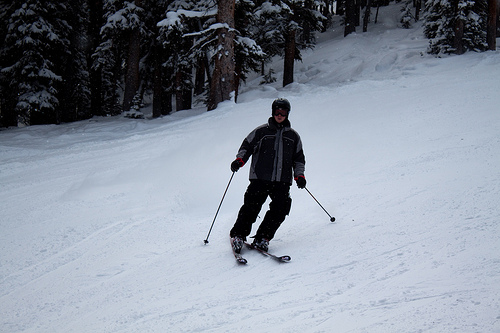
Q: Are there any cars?
A: No, there are no cars.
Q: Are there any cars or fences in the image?
A: No, there are no cars or fences.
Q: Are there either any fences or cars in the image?
A: No, there are no cars or fences.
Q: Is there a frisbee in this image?
A: No, there are no frisbees.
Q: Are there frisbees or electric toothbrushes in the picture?
A: No, there are no frisbees or electric toothbrushes.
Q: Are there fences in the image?
A: No, there are no fences.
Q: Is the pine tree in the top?
A: Yes, the pine tree is in the top of the image.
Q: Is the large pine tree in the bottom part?
A: No, the pine tree is in the top of the image.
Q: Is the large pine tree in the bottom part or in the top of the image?
A: The pine tree is in the top of the image.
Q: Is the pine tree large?
A: Yes, the pine tree is large.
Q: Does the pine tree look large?
A: Yes, the pine tree is large.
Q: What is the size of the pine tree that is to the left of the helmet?
A: The pine tree is large.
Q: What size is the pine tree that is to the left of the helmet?
A: The pine tree is large.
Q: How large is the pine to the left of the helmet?
A: The pine is large.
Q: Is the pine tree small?
A: No, the pine tree is large.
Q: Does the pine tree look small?
A: No, the pine tree is large.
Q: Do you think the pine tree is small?
A: No, the pine tree is large.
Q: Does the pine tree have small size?
A: No, the pine tree is large.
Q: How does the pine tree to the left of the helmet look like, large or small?
A: The pine tree is large.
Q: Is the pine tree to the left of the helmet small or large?
A: The pine tree is large.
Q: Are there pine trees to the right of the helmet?
A: No, the pine tree is to the left of the helmet.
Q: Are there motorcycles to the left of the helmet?
A: No, there is a pine tree to the left of the helmet.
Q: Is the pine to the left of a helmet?
A: Yes, the pine is to the left of a helmet.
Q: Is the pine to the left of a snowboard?
A: No, the pine is to the left of a helmet.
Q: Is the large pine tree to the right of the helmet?
A: No, the pine is to the left of the helmet.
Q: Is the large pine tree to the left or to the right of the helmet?
A: The pine is to the left of the helmet.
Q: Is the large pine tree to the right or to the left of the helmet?
A: The pine is to the left of the helmet.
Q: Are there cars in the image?
A: No, there are no cars.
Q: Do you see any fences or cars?
A: No, there are no cars or fences.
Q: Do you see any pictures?
A: No, there are no pictures.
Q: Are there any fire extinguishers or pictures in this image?
A: No, there are no pictures or fire extinguishers.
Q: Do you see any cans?
A: No, there are no cans.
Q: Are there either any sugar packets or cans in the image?
A: No, there are no cans or sugar packets.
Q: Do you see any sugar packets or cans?
A: No, there are no cans or sugar packets.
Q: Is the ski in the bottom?
A: Yes, the ski is in the bottom of the image.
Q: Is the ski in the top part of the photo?
A: No, the ski is in the bottom of the image.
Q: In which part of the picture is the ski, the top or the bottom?
A: The ski is in the bottom of the image.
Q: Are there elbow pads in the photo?
A: No, there are no elbow pads.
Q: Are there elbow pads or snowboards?
A: No, there are no elbow pads or snowboards.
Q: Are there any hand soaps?
A: No, there are no hand soaps.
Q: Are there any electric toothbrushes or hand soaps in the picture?
A: No, there are no hand soaps or electric toothbrushes.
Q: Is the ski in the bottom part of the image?
A: Yes, the ski is in the bottom of the image.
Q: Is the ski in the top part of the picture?
A: No, the ski is in the bottom of the image.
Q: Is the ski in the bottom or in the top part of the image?
A: The ski is in the bottom of the image.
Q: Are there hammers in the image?
A: No, there are no hammers.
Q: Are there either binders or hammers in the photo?
A: No, there are no hammers or binders.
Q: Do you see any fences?
A: No, there are no fences.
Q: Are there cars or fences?
A: No, there are no fences or cars.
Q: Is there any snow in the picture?
A: Yes, there is snow.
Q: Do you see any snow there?
A: Yes, there is snow.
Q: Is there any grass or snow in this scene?
A: Yes, there is snow.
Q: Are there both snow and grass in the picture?
A: No, there is snow but no grass.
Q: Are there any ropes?
A: No, there are no ropes.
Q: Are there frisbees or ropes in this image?
A: No, there are no ropes or frisbees.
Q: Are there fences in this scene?
A: No, there are no fences.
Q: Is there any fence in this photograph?
A: No, there are no fences.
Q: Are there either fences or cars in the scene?
A: No, there are no fences or cars.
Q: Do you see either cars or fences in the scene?
A: No, there are no fences or cars.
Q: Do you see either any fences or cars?
A: No, there are no fences or cars.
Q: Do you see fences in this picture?
A: No, there are no fences.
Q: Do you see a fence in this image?
A: No, there are no fences.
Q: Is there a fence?
A: No, there are no fences.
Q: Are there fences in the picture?
A: No, there are no fences.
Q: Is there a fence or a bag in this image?
A: No, there are no fences or bags.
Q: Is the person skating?
A: Yes, the person is skating.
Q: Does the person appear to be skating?
A: Yes, the person is skating.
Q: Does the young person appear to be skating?
A: Yes, the person is skating.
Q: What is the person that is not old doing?
A: The person is skating.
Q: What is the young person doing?
A: The person is skating.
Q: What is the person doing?
A: The person is skating.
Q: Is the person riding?
A: No, the person is skating.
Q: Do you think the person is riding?
A: No, the person is skating.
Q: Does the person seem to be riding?
A: No, the person is skating.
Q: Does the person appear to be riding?
A: No, the person is skating.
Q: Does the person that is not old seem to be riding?
A: No, the person is skating.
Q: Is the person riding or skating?
A: The person is skating.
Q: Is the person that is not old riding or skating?
A: The person is skating.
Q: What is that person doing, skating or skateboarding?
A: The person is skating.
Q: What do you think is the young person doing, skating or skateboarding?
A: The person is skating.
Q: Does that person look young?
A: Yes, the person is young.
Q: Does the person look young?
A: Yes, the person is young.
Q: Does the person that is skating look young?
A: Yes, the person is young.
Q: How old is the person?
A: The person is young.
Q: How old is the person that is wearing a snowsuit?
A: The person is young.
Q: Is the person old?
A: No, the person is young.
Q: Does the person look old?
A: No, the person is young.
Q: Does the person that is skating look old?
A: No, the person is young.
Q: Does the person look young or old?
A: The person is young.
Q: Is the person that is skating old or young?
A: The person is young.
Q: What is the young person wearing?
A: The person is wearing a snow suit.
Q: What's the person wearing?
A: The person is wearing a snow suit.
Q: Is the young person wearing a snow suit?
A: Yes, the person is wearing a snow suit.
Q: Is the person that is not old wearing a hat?
A: No, the person is wearing a snow suit.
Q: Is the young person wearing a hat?
A: No, the person is wearing a snow suit.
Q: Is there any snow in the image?
A: Yes, there is snow.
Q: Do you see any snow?
A: Yes, there is snow.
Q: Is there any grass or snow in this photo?
A: Yes, there is snow.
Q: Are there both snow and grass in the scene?
A: No, there is snow but no grass.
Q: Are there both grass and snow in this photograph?
A: No, there is snow but no grass.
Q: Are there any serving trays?
A: No, there are no serving trays.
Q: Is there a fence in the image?
A: No, there are no fences.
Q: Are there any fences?
A: No, there are no fences.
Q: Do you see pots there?
A: No, there are no pots.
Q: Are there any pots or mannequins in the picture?
A: No, there are no pots or mannequins.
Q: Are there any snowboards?
A: No, there are no snowboards.